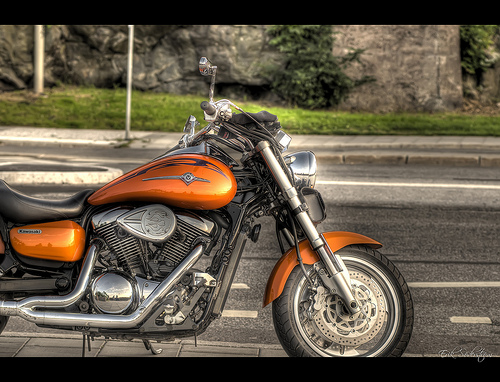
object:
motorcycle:
[1, 47, 421, 365]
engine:
[85, 206, 218, 335]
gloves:
[228, 107, 284, 137]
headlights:
[282, 146, 322, 193]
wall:
[1, 22, 500, 112]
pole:
[121, 25, 141, 144]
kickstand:
[139, 336, 170, 357]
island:
[1, 152, 128, 189]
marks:
[90, 156, 234, 198]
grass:
[0, 84, 497, 140]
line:
[401, 274, 499, 292]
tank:
[82, 146, 244, 216]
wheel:
[266, 239, 423, 368]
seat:
[0, 175, 96, 230]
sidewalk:
[3, 326, 454, 363]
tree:
[259, 25, 375, 120]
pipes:
[0, 237, 211, 334]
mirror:
[194, 53, 220, 84]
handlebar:
[196, 97, 219, 117]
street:
[0, 150, 498, 348]